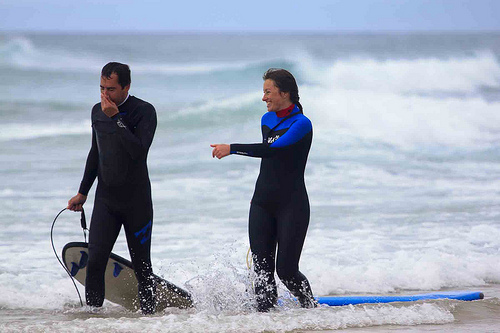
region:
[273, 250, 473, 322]
a bright blue surfboard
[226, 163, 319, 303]
woman is wearing black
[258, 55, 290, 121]
woman has on red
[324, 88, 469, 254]
large white water waves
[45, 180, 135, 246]
man is holding cord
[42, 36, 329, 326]
couple in the ater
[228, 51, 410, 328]
a woman in the ater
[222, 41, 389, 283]
a woman wearing wetsuit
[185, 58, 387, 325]
a woman wearing blue and black wet suit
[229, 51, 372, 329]
blue and black wetsuit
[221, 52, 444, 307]
a woman dragging a surfboard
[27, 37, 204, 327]
a man in the water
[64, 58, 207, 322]
a man walking in the water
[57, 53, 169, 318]
a man dragging surfboard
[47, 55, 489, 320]
two surfers make their way to shore on foot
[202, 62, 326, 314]
the lady looks to be enjoying herself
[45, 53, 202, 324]
the gentleman looks a little waterlogged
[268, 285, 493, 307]
the lady's surfboard is blue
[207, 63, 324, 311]
the lady is wearing a wetsuit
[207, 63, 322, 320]
the lady's wetsuit has blue trim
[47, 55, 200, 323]
the gentleman is wearing a wetsuit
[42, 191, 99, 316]
the gentleman is wearing a cable attaching him to his board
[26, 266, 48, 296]
white wave in water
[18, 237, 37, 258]
white wave in water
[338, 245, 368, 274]
white wave in water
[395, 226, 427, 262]
white wave in water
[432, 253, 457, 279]
white wave in water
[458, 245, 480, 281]
white wave in water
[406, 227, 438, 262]
white wave in water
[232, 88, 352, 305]
woman wearing black and blue wetsuit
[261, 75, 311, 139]
woman has hair in ponytail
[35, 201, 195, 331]
man is dragging boogie board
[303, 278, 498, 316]
woman has a blue board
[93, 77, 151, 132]
man is holding his nose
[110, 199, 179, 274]
man is wearing wetsuit with blue marks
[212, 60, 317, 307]
a person is standing up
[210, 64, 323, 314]
a person is playing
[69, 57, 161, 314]
a person is standing up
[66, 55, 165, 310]
a person is playing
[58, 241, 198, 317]
a surfboard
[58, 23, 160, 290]
a person in the water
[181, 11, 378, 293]
a person pulling the surfboard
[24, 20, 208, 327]
a person pulling a surfboard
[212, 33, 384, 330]
a person wearing a wetsuit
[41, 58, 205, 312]
a person wearing a wetsuit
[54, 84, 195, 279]
wetsuit is black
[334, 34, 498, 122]
a wave on the water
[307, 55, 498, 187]
a wave on the water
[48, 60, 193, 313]
man in wetsuit with body board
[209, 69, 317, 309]
woman in blue and black wetsuit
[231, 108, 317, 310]
Woman's black and blue wetsuit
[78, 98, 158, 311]
Men's black wetsuit with blue stripes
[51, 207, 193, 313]
Black and white body board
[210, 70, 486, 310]
Woman at beach with body board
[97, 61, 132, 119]
Man touching his face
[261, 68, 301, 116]
Woman's smiling face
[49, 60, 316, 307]
Two people in wetsuits at the beach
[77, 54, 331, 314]
a man and woman standing in water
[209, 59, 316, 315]
a woman standing in water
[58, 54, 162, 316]
a man standing in water